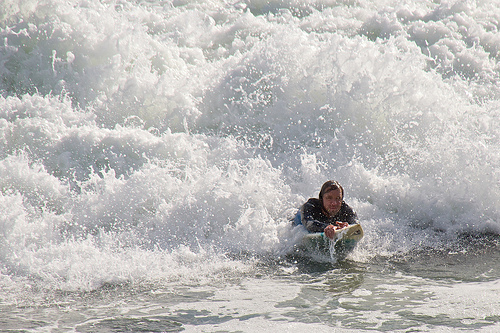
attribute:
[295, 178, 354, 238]
man — surfing, white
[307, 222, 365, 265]
surfboard — yellow, blue, white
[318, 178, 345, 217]
hair — brown, blond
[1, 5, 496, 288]
wave — choppy, violent, large, crashing, white, foaming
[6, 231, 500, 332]
water — calm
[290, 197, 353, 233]
wetsuit — black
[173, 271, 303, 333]
sud — white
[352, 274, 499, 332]
sud — white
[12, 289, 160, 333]
sud — white